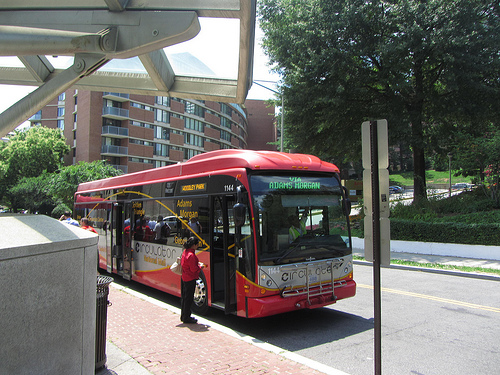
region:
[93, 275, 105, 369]
a black trash bin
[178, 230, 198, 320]
a person wearing a red shirt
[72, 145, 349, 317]
a red and white bus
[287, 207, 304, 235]
the driver of the bus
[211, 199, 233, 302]
the door of the bus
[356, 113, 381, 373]
a street sign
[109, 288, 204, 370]
the sidewalk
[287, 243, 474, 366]
the street the bus is on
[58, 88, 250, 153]
a building behind the bus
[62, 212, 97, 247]
people walking next to the bus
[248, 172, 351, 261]
the front windshield of the city bus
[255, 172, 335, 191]
the bus route destination display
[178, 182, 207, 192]
the bus route display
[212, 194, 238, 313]
the city buses front side door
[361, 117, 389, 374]
a street sign at the curb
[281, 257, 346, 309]
a bicycle rack on the front bumper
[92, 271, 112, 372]
a public trash can on the sidewalk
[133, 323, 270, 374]
a red brick walkway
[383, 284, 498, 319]
a yellow traffic line painted on the street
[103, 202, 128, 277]
the city buses rear side door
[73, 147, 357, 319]
A red bus that says ADAMS MORGAN on the front.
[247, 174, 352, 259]
A large glass windshield on a bus.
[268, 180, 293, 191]
The green word ADAMS on a bus.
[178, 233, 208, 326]
A woman in a red shirt with black hair.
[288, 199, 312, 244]
A male bus driver with his left hand in the air.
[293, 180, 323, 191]
The green word MORGAN on the bus.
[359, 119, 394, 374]
The back of three signs on a green pole.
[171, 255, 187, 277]
A white purse a woman in red is holding.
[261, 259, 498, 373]
A grey road with two double yellow lines in the center.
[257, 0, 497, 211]
A tall green and brown tree growing.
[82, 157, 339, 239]
a bus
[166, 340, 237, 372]
the sidewalk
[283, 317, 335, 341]
a shadow under the bus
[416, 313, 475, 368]
the street is grey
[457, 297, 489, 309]
a yellow line in the street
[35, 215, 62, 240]
a shadow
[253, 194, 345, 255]
windshield of the bus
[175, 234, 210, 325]
a women standing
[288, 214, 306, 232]
driver of the bus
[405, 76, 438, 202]
a tree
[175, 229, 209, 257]
head of a person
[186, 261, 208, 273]
arm of a person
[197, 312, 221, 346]
shadow of a person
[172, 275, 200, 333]
leg of a person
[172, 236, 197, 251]
hair of a person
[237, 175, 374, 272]
window of a bus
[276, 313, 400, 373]
shadow of a bus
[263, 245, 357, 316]
bumper of a bus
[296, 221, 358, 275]
wipers of a bus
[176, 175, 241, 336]
door of a bus